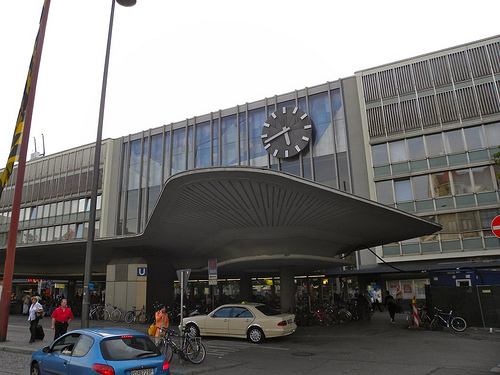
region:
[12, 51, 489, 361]
outside of the entrance to a large shopping complex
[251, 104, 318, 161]
a huge clock on the top of the building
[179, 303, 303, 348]
a cream colored car parked at the entrance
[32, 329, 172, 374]
a small blue car driving in the road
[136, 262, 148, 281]
a blue sign with a white U on it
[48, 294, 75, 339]
a man in a red shirt and black pants crossing the street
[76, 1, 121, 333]
a very tall silver lightpost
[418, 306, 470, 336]
a bicycle leaning against a fence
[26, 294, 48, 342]
a woman in a white shirt wheeling a black suitcase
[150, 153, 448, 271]
a large curved over hang at the entrance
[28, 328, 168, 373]
blue car in the foreground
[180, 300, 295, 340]
yellow car at the curb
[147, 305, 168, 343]
person in the orange jacket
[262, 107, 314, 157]
clock on the side of the building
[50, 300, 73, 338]
man in a red shirt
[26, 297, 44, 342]
woman in white blouse rolling luggage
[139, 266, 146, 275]
blue sign with the letter U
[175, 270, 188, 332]
back of a triangular yield sign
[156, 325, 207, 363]
two bikes next to the blue car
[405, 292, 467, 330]
bikes next to a red and white striped pole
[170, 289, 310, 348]
White car is parked next to building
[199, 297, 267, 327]
White car has windows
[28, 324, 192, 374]
Blue car is on the street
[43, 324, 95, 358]
Blue car has windows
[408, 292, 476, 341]
Bike parked next to a traffic cone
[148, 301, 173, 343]
Woman is wearing an orange dress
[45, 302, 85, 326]
Man is wearing a red shirt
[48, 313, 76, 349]
Man is wearing black pants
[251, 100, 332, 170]
Clock is located on front of building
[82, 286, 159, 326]
Bikes are parked next to the building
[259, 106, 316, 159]
Black clock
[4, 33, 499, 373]
Building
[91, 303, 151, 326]
Group of bicycles in a row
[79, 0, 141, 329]
Light post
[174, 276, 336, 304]
Several doors that leads into the building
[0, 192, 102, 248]
Several rectangular shaped windows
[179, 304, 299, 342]
Small white Mercedes vehicle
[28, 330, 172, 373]
Small one door car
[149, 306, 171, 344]
Lady with an orange handbag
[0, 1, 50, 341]
Flag on a brown pole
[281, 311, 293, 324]
back of a car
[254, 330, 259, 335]
wheel of a car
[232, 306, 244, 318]
window of a car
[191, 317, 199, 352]
edge of a wheel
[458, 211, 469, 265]
part of a windolw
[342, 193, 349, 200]
top of a roof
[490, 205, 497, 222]
part of a sign post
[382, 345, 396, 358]
edge of a road